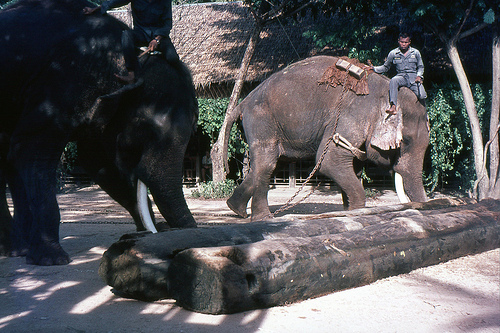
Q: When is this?
A: Daytime.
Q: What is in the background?
A: Foliage and a hut.